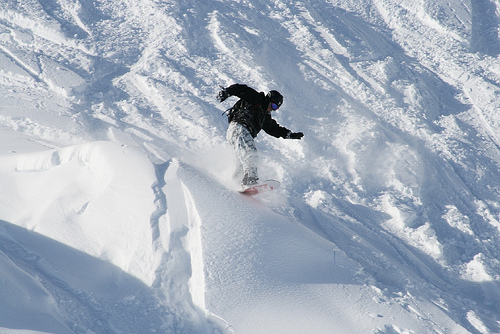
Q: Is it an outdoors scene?
A: Yes, it is outdoors.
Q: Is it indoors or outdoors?
A: It is outdoors.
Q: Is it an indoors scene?
A: No, it is outdoors.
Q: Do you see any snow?
A: Yes, there is snow.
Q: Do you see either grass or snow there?
A: Yes, there is snow.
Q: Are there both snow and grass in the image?
A: No, there is snow but no grass.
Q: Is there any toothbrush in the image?
A: No, there are no toothbrushes.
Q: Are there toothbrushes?
A: No, there are no toothbrushes.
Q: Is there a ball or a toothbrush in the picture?
A: No, there are no toothbrushes or balls.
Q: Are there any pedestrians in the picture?
A: No, there are no pedestrians.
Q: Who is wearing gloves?
A: The boy is wearing gloves.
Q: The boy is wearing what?
A: The boy is wearing gloves.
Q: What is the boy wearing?
A: The boy is wearing gloves.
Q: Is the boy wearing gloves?
A: Yes, the boy is wearing gloves.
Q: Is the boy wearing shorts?
A: No, the boy is wearing gloves.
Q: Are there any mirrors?
A: No, there are no mirrors.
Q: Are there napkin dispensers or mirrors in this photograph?
A: No, there are no mirrors or napkin dispensers.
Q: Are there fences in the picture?
A: No, there are no fences.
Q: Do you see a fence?
A: No, there are no fences.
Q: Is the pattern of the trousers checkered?
A: Yes, the trousers are checkered.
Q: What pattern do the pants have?
A: The pants have checkered pattern.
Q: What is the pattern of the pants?
A: The pants are checkered.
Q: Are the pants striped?
A: No, the pants are checkered.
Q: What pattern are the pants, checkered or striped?
A: The pants are checkered.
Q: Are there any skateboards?
A: No, there are no skateboards.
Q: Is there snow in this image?
A: Yes, there is snow.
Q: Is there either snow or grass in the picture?
A: Yes, there is snow.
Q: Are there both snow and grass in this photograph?
A: No, there is snow but no grass.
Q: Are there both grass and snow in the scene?
A: No, there is snow but no grass.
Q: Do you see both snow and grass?
A: No, there is snow but no grass.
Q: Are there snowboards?
A: Yes, there is a snowboard.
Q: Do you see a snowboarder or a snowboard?
A: Yes, there is a snowboard.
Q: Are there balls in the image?
A: No, there are no balls.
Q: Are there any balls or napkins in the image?
A: No, there are no balls or napkins.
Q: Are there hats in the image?
A: Yes, there is a hat.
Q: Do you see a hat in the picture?
A: Yes, there is a hat.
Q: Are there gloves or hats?
A: Yes, there is a hat.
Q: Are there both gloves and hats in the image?
A: Yes, there are both a hat and gloves.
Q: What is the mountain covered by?
A: The mountain is covered by the snow.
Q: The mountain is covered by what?
A: The mountain is covered by the snow.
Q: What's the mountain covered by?
A: The mountain is covered by the snow.